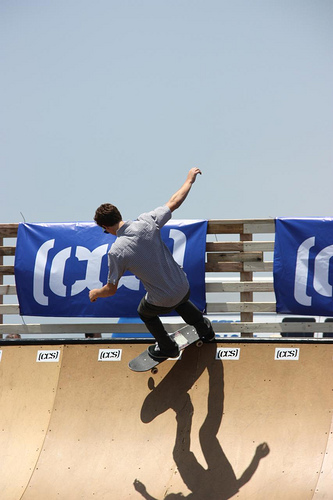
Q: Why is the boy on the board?
A: He's skateboarding.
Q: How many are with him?
A: None.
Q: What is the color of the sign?
A: Blue.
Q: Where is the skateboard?
A: Under his feet.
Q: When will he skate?
A: Now.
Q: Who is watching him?
A: Nobody.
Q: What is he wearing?
A: Sunglasses.